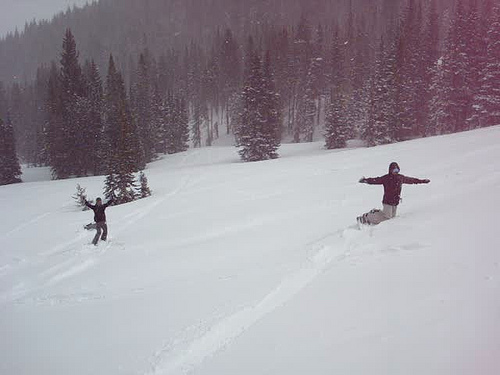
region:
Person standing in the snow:
[70, 185, 124, 252]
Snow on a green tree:
[237, 33, 277, 146]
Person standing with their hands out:
[364, 149, 424, 191]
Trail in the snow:
[234, 241, 319, 332]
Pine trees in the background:
[171, 48, 258, 135]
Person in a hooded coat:
[377, 157, 404, 198]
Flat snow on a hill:
[324, 287, 402, 341]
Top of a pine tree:
[99, 50, 126, 80]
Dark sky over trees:
[11, 50, 43, 75]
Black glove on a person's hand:
[419, 176, 431, 188]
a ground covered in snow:
[132, 250, 344, 371]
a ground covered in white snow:
[244, 258, 437, 371]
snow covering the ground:
[159, 234, 409, 368]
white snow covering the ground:
[142, 220, 419, 370]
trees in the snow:
[53, 26, 383, 260]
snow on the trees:
[119, 19, 371, 161]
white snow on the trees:
[178, 15, 305, 105]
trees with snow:
[115, 48, 335, 167]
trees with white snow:
[159, 73, 499, 190]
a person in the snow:
[322, 104, 468, 371]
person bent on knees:
[358, 160, 411, 227]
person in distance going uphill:
[82, 191, 115, 248]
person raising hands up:
[83, 189, 119, 221]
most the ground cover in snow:
[0, 248, 497, 373]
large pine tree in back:
[233, 91, 282, 160]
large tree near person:
[98, 88, 144, 205]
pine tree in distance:
[320, 86, 351, 151]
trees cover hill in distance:
[1, 0, 492, 42]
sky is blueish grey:
[6, 2, 42, 29]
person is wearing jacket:
[378, 169, 407, 205]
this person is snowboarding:
[318, 150, 446, 240]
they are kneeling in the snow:
[328, 135, 438, 248]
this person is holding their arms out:
[340, 138, 462, 248]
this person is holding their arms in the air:
[65, 175, 130, 267]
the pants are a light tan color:
[350, 193, 406, 231]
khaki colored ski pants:
[352, 193, 420, 224]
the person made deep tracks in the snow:
[147, 210, 407, 367]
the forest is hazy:
[5, 3, 482, 163]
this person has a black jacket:
[68, 173, 120, 263]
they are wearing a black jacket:
[65, 181, 133, 253]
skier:
[70, 185, 111, 239]